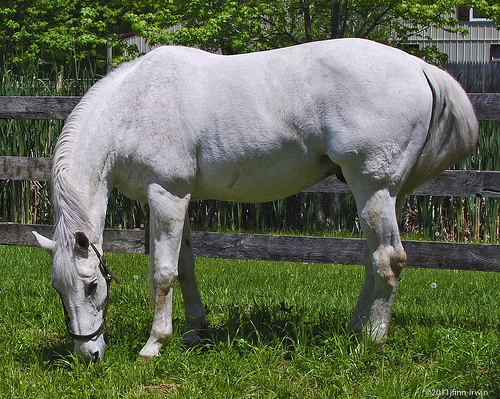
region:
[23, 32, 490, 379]
white horse eating grass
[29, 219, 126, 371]
white horse face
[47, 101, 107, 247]
white horse hair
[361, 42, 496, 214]
horse tail between legs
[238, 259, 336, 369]
bright green healthy grass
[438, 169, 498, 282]
two wooden beams on fence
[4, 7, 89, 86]
green leaf tree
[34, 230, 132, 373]
horse face brown strap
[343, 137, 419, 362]
white horse with dirt on legs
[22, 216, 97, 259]
white horse pointy ears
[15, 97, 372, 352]
the horse is white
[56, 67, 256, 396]
the horse is white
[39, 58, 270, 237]
the horse is white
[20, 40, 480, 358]
White horse eating grass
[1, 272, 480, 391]
Low cut green grass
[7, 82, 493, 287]
Faded wooden fence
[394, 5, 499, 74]
Tan colored building through the trees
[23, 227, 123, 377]
Leather halter on the horse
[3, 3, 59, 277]
Green trees and tall grasses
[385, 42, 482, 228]
Horse tail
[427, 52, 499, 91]
Row of pointy fence boards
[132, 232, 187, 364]
White horse leg with brown at the knee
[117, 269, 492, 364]
Shadow on the ground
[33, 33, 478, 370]
a white horse eating grass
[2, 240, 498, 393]
grass under a horse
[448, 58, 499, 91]
a privacy fenc around a house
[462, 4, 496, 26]
the window of a house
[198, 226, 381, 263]
a weathered board on a horse fence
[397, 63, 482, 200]
the tail of a horse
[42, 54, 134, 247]
the mane of a horse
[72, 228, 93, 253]
the ear of a horse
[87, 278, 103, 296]
the eye of a horse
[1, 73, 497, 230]
a field of corn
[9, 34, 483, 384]
Well groomed horse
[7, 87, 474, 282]
Old wood fence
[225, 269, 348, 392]
Healthy green grass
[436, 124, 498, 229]
Tall stalks of grass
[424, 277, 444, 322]
Lonely dandelion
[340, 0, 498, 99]
Barn hidden in the back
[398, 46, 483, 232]
Horse's tail tucked between his legs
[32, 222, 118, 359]
The horse is wearing a face harness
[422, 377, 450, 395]
The picture was taken in 2011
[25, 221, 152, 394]
The horse is focused on the tasty grass